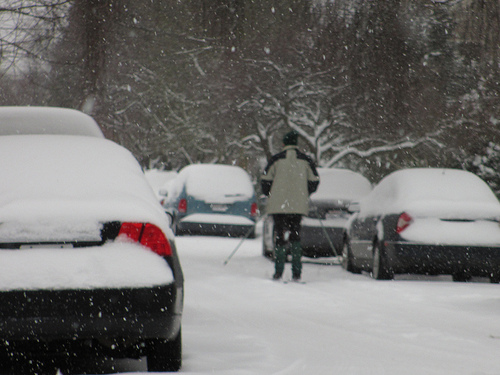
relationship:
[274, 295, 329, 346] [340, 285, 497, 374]
snow on ground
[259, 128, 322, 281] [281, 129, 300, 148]
person wearing hat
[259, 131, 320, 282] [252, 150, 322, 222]
person wearing coat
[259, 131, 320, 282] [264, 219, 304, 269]
person wearing pants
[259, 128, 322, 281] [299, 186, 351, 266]
person holding pole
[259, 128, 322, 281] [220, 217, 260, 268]
person holding ski poles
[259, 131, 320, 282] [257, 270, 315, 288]
person has snow shoes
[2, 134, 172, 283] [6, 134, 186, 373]
snow on car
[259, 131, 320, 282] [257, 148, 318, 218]
person with a coat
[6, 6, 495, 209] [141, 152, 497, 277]
trees next to cars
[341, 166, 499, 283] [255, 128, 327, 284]
car parked next to man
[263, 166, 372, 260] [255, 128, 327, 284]
car parked next to man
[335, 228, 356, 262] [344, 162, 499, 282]
tire of car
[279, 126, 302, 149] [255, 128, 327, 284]
hat on man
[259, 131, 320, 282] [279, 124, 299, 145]
person wearing hat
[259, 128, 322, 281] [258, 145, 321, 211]
person wearing coat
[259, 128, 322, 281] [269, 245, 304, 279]
person wearing shoes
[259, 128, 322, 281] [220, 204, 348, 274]
person holding poles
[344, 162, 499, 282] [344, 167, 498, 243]
car covered in snow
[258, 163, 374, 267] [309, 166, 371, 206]
car covered in snow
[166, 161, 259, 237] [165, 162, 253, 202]
car covered in snow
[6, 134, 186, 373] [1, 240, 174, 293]
car covered in snow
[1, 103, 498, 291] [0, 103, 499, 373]
snow on cars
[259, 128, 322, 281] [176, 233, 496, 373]
person in snow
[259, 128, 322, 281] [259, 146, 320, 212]
person wearing top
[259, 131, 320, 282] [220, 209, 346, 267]
person holding ski poles